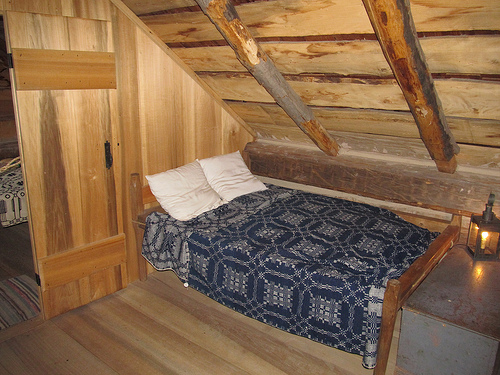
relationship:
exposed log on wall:
[363, 3, 461, 177] [128, 9, 498, 277]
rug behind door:
[1, 270, 47, 329] [1, 8, 142, 328]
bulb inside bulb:
[473, 225, 498, 253] [464, 192, 499, 262]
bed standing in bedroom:
[205, 196, 462, 314] [1, 1, 497, 374]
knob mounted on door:
[108, 154, 114, 165] [1, 8, 142, 328]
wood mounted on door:
[10, 40, 115, 100] [1, 8, 142, 328]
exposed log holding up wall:
[361, 0, 457, 174] [113, 1, 498, 339]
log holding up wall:
[194, 0, 339, 157] [113, 1, 498, 339]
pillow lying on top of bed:
[143, 159, 230, 224] [183, 128, 417, 373]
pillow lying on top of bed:
[145, 150, 268, 221] [129, 168, 461, 373]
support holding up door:
[36, 230, 126, 290] [1, 8, 142, 328]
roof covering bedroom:
[110, 0, 484, 174] [11, 121, 498, 372]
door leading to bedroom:
[1, 8, 142, 328] [0, 2, 484, 372]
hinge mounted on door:
[5, 51, 15, 69] [1, 8, 142, 328]